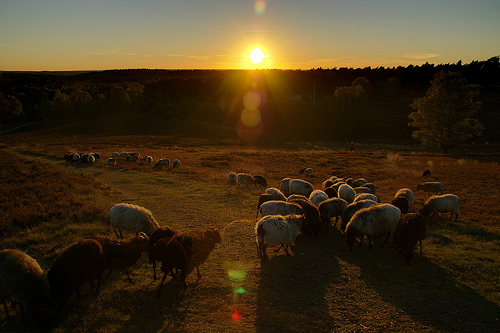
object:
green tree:
[407, 69, 481, 162]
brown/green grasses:
[13, 162, 89, 217]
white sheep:
[106, 200, 159, 235]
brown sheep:
[141, 224, 229, 286]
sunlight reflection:
[233, 71, 267, 136]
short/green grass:
[447, 238, 500, 273]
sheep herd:
[253, 174, 462, 259]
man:
[346, 138, 359, 154]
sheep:
[138, 223, 195, 285]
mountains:
[0, 53, 499, 147]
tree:
[428, 71, 471, 95]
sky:
[301, 0, 436, 45]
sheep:
[419, 193, 464, 222]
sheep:
[236, 172, 255, 187]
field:
[0, 132, 499, 332]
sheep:
[1, 248, 54, 311]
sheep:
[171, 158, 186, 168]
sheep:
[390, 212, 428, 261]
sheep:
[283, 178, 314, 195]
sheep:
[256, 200, 305, 218]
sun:
[241, 36, 274, 68]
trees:
[48, 80, 150, 105]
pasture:
[0, 134, 495, 331]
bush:
[399, 149, 471, 167]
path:
[1, 133, 499, 332]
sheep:
[103, 155, 121, 169]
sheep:
[254, 211, 306, 261]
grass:
[2, 151, 62, 223]